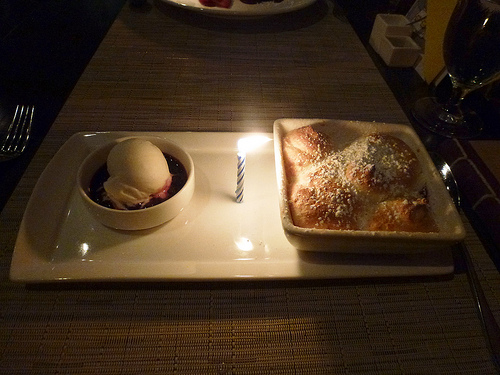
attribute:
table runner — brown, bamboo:
[4, 3, 495, 369]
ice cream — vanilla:
[102, 138, 172, 204]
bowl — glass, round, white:
[75, 136, 192, 233]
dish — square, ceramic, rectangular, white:
[271, 116, 466, 256]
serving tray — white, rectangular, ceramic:
[9, 123, 456, 280]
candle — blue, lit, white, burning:
[231, 127, 272, 206]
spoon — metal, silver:
[428, 146, 495, 357]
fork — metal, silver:
[4, 98, 37, 164]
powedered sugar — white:
[311, 138, 405, 218]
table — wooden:
[4, 0, 500, 371]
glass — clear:
[414, 3, 495, 141]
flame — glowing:
[233, 124, 273, 153]